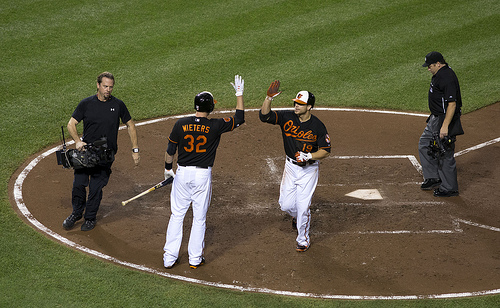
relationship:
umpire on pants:
[418, 50, 463, 196] [415, 110, 457, 193]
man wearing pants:
[159, 74, 247, 269] [162, 161, 214, 267]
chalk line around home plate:
[262, 144, 463, 239] [344, 183, 382, 203]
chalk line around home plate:
[445, 133, 497, 161] [344, 183, 382, 203]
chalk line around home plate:
[455, 210, 497, 235] [344, 183, 382, 203]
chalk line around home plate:
[12, 101, 497, 301] [344, 183, 382, 203]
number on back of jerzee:
[168, 125, 231, 159] [165, 107, 246, 168]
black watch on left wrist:
[132, 146, 140, 153] [130, 145, 140, 155]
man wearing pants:
[259, 79, 332, 252] [273, 146, 325, 253]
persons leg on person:
[163, 171, 204, 266] [161, 107, 218, 275]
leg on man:
[186, 200, 209, 265] [159, 74, 247, 269]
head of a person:
[96, 72, 113, 100] [61, 71, 141, 232]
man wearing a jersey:
[159, 72, 247, 269] [165, 111, 233, 169]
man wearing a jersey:
[262, 71, 332, 250] [271, 107, 334, 167]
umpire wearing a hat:
[401, 32, 473, 205] [418, 45, 454, 74]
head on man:
[284, 83, 317, 127] [259, 79, 332, 252]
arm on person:
[65, 97, 88, 151] [61, 71, 141, 232]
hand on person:
[127, 149, 144, 166] [43, 61, 148, 238]